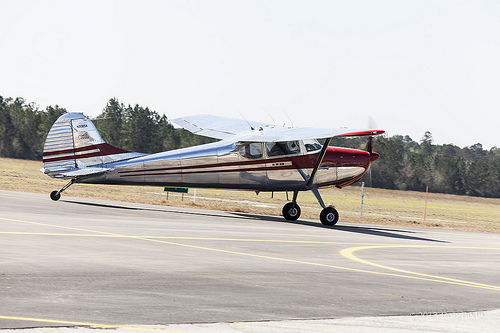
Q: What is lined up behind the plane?
A: Trees.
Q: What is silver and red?
A: The airplane.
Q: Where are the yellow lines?
A: On the runway.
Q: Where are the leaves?
A: On the tree.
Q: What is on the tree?
A: Leaves.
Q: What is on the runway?
A: Plane.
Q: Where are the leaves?
A: Under plane.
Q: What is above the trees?
A: Sky.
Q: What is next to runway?
A: Grass.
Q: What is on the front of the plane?
A: Propeller.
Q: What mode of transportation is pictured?
A: An airplane.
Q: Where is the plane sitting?
A: On a runway.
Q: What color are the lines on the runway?
A: Yellow.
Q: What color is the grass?
A: Brown and yellow.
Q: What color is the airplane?
A: Silver and red.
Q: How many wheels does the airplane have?
A: Three.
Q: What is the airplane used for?
A: Flying.